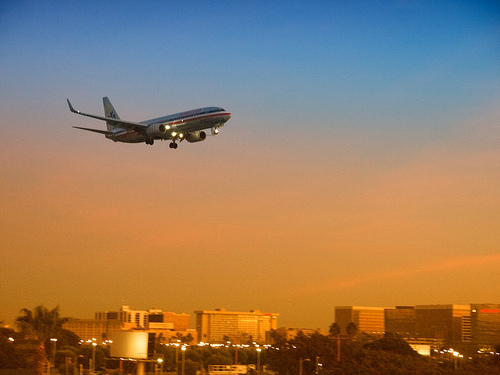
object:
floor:
[0, 0, 500, 311]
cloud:
[2, 139, 494, 319]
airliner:
[66, 96, 228, 148]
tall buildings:
[270, 322, 317, 342]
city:
[2, 299, 498, 374]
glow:
[0, 140, 490, 334]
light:
[213, 127, 218, 132]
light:
[179, 133, 184, 138]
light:
[170, 130, 177, 136]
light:
[163, 123, 170, 129]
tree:
[9, 293, 74, 362]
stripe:
[161, 111, 230, 119]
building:
[475, 315, 499, 349]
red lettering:
[475, 307, 497, 314]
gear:
[164, 142, 176, 150]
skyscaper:
[196, 297, 274, 342]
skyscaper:
[333, 299, 380, 336]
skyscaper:
[382, 297, 466, 344]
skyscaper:
[469, 303, 499, 348]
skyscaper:
[92, 302, 149, 334]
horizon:
[2, 313, 499, 348]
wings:
[63, 98, 147, 131]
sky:
[0, 0, 497, 344]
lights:
[48, 335, 62, 344]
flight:
[29, 39, 424, 200]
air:
[5, 8, 483, 326]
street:
[4, 349, 494, 375]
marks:
[109, 118, 128, 132]